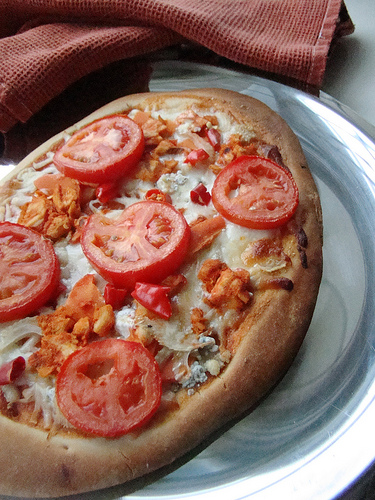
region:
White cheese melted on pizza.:
[211, 247, 237, 266]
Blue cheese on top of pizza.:
[182, 367, 203, 390]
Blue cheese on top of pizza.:
[163, 173, 190, 198]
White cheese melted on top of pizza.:
[68, 247, 93, 284]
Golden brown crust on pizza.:
[259, 307, 292, 375]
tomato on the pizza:
[216, 150, 298, 235]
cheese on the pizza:
[22, 385, 54, 420]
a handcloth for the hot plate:
[186, 3, 357, 89]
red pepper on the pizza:
[186, 184, 214, 210]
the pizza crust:
[167, 385, 235, 461]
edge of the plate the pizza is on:
[324, 93, 372, 186]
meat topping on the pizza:
[47, 300, 85, 351]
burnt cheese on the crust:
[262, 273, 300, 296]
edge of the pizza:
[187, 68, 282, 161]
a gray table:
[346, 42, 370, 88]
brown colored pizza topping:
[177, 111, 207, 130]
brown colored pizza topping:
[139, 116, 166, 141]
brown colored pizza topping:
[152, 139, 167, 159]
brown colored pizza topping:
[31, 339, 69, 373]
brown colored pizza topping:
[189, 306, 206, 334]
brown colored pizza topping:
[209, 267, 242, 308]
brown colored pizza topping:
[198, 256, 225, 291]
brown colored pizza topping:
[35, 309, 70, 337]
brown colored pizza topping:
[62, 274, 101, 322]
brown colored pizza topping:
[89, 304, 117, 333]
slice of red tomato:
[207, 150, 304, 227]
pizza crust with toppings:
[11, 85, 320, 495]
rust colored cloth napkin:
[6, 1, 345, 89]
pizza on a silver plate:
[111, 57, 374, 498]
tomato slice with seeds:
[82, 191, 197, 291]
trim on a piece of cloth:
[303, 0, 352, 94]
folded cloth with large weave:
[24, 0, 350, 85]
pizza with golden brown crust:
[7, 86, 328, 495]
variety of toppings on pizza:
[17, 73, 326, 493]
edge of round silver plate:
[233, 47, 373, 177]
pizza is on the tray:
[56, 60, 360, 246]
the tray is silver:
[162, 402, 345, 496]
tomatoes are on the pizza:
[36, 306, 286, 483]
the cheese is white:
[156, 306, 257, 383]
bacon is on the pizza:
[48, 287, 138, 339]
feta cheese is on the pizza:
[152, 172, 250, 197]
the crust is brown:
[16, 423, 142, 480]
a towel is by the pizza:
[36, 14, 187, 89]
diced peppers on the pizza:
[145, 118, 252, 235]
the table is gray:
[339, 49, 370, 98]